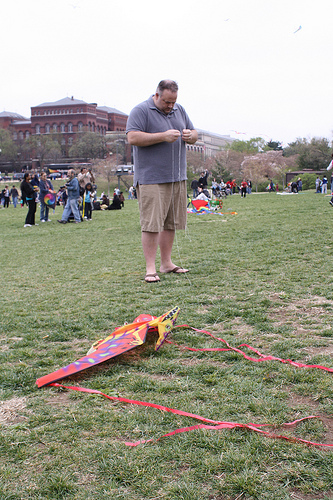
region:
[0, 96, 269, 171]
large red brick institutional building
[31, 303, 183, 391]
colorful dragon kite on ground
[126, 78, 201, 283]
man in shorts and flip flops focused on kite string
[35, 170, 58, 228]
blue jean clad woman holding a kite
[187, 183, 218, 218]
person sitting in lawn chair surrounded by kites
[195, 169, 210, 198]
man shading eyes while looking up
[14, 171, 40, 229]
woman in black holding a small child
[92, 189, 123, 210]
group of people sitting on the grass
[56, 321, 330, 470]
red ribbons trailing from dragon kite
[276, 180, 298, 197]
people sitting on a white blanket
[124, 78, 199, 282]
older man attempting to fix kite string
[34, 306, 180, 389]
red, purple, and yellow kite on park ground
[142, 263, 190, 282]
man's feet wearing brown flip flops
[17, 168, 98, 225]
group of people standing with kite at park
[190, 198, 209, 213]
red kite on ground in background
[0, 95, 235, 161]
brick buildings in background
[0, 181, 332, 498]
green grass on park field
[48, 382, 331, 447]
red kite tail attached to kite on ground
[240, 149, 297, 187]
brown and bare tree in park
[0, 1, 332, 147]
cloudy white sky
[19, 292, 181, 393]
large red kite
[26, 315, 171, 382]
kite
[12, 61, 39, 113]
white clouds in blue sky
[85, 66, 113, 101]
white clouds in blue sky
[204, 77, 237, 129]
white clouds in blue sky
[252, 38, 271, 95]
white clouds in blue sky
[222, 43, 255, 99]
white clouds in blue sky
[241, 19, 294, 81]
white clouds in blue sky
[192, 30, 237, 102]
white clouds in blue sky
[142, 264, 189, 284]
Man is wearing shoes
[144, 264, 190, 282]
Man is wearing brown shoes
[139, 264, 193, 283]
Man is wearing sandals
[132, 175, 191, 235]
Man is wearing shorts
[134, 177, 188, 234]
Man is wearing brown shorts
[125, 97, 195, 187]
Man is wearing a shirt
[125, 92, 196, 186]
Man is wearing a gray shirt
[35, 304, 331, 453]
Kite is on the ground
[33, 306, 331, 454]
Kite is on the grass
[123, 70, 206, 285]
man working on kite string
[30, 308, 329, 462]
brightly colored kite on the ground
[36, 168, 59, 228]
woman holding brightly colored circular object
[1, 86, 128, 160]
large red brick building in background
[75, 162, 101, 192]
man holding a camera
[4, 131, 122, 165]
row of trees by building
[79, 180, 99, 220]
child walking towards camera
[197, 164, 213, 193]
man holding object in upraised arm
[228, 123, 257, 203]
person with airborne kite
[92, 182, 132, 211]
group of seated people